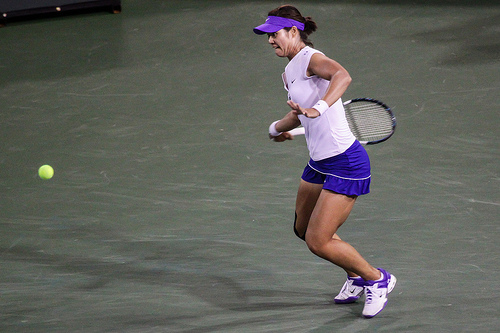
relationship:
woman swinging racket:
[252, 4, 404, 318] [277, 94, 397, 148]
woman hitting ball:
[252, 4, 404, 318] [35, 161, 57, 181]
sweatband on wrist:
[312, 98, 329, 115] [308, 98, 336, 121]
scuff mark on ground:
[128, 223, 260, 259] [4, 0, 498, 332]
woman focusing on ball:
[252, 4, 404, 318] [35, 161, 57, 181]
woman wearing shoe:
[252, 4, 404, 318] [358, 267, 403, 318]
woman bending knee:
[252, 4, 404, 318] [299, 227, 346, 255]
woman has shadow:
[252, 4, 404, 318] [14, 226, 359, 308]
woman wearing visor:
[252, 4, 404, 318] [245, 16, 304, 34]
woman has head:
[252, 4, 404, 318] [255, 3, 307, 62]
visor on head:
[245, 16, 304, 34] [255, 3, 307, 62]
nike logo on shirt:
[287, 72, 299, 86] [275, 46, 357, 164]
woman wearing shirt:
[252, 4, 404, 318] [275, 46, 357, 164]